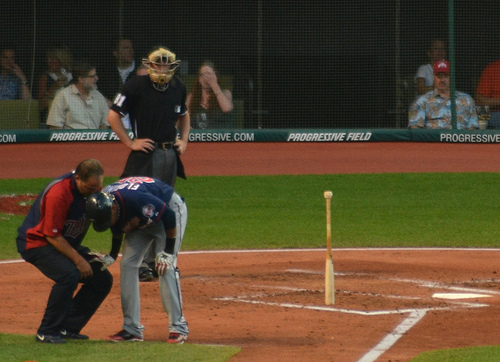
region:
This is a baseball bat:
[253, 140, 363, 338]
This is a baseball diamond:
[256, 239, 348, 350]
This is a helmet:
[123, 53, 186, 91]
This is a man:
[417, 64, 497, 105]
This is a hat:
[419, 66, 452, 85]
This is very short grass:
[284, 171, 414, 301]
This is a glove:
[154, 231, 218, 298]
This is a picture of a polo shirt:
[4, 171, 124, 255]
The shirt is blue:
[114, 188, 145, 220]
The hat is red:
[413, 51, 449, 86]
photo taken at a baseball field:
[10, 18, 477, 351]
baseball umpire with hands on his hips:
[123, 41, 195, 182]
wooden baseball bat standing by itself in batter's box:
[313, 178, 346, 302]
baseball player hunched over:
[88, 169, 197, 334]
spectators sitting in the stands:
[26, 31, 495, 128]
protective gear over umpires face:
[134, 43, 184, 95]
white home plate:
[420, 272, 495, 310]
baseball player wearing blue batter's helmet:
[77, 185, 125, 241]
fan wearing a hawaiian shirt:
[407, 55, 475, 130]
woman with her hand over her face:
[181, 53, 242, 126]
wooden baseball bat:
[323, 189, 338, 307]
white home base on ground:
[428, 286, 492, 300]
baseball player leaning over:
[83, 173, 192, 346]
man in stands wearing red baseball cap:
[408, 58, 480, 127]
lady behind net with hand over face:
[186, 60, 238, 127]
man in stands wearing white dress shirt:
[45, 62, 110, 129]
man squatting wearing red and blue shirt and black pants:
[14, 154, 114, 347]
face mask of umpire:
[141, 47, 181, 85]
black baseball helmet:
[83, 188, 112, 232]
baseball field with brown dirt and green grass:
[1, 142, 499, 360]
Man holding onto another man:
[15, 159, 189, 344]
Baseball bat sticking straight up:
[319, 187, 339, 305]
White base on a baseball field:
[429, 288, 494, 302]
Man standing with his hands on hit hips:
[105, 47, 190, 281]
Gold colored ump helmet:
[139, 48, 182, 86]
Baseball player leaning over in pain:
[81, 175, 189, 345]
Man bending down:
[16, 157, 114, 344]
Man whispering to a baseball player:
[15, 159, 192, 344]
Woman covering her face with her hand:
[181, 62, 237, 127]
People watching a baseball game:
[4, 34, 499, 132]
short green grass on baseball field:
[204, 175, 244, 207]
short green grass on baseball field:
[231, 200, 274, 227]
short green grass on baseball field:
[360, 185, 400, 221]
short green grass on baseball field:
[411, 178, 453, 216]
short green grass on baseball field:
[426, 174, 479, 219]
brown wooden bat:
[307, 182, 347, 329]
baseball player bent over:
[90, 175, 200, 347]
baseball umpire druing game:
[100, 36, 195, 148]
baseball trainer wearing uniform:
[7, 148, 111, 340]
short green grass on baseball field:
[112, 342, 152, 359]